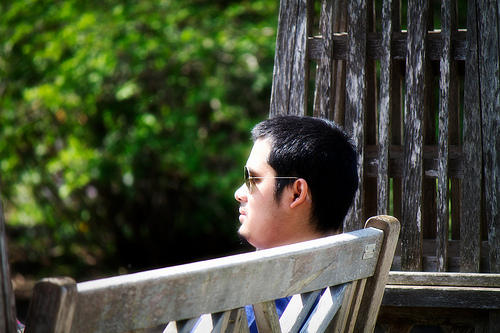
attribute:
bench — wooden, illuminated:
[23, 212, 403, 323]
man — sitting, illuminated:
[233, 110, 363, 332]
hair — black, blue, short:
[246, 113, 360, 237]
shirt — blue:
[242, 286, 329, 332]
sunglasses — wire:
[242, 162, 312, 204]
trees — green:
[1, 0, 473, 290]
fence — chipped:
[265, 1, 490, 317]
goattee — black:
[235, 226, 252, 242]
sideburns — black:
[274, 182, 294, 209]